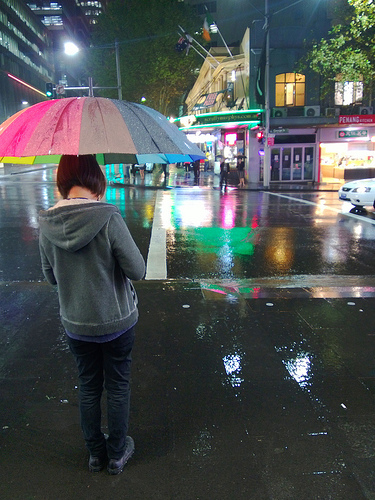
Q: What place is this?
A: It is a sidewalk.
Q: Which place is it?
A: It is a sidewalk.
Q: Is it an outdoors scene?
A: Yes, it is outdoors.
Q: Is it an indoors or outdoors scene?
A: It is outdoors.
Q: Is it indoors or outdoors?
A: It is outdoors.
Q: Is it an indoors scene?
A: No, it is outdoors.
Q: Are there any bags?
A: No, there are no bags.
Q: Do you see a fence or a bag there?
A: No, there are no bags or fences.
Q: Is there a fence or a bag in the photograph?
A: No, there are no bags or fences.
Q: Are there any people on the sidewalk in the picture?
A: Yes, there are people on the sidewalk.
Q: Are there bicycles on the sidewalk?
A: No, there are people on the sidewalk.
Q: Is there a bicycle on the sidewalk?
A: No, there are people on the sidewalk.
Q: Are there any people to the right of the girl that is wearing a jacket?
A: Yes, there are people to the right of the girl.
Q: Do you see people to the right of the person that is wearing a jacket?
A: Yes, there are people to the right of the girl.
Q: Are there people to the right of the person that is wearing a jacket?
A: Yes, there are people to the right of the girl.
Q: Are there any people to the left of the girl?
A: No, the people are to the right of the girl.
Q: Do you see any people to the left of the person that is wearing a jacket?
A: No, the people are to the right of the girl.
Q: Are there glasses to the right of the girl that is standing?
A: No, there are people to the right of the girl.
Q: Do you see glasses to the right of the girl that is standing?
A: No, there are people to the right of the girl.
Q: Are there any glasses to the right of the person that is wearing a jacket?
A: No, there are people to the right of the girl.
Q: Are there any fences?
A: No, there are no fences.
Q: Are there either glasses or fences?
A: No, there are no fences or glasses.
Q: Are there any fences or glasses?
A: No, there are no fences or glasses.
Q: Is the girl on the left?
A: Yes, the girl is on the left of the image.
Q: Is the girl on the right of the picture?
A: No, the girl is on the left of the image.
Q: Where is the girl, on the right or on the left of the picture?
A: The girl is on the left of the image.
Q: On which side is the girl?
A: The girl is on the left of the image.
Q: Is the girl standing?
A: Yes, the girl is standing.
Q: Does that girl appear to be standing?
A: Yes, the girl is standing.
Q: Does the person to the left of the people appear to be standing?
A: Yes, the girl is standing.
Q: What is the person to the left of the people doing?
A: The girl is standing.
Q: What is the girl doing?
A: The girl is standing.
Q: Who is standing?
A: The girl is standing.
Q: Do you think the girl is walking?
A: No, the girl is standing.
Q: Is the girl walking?
A: No, the girl is standing.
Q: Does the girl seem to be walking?
A: No, the girl is standing.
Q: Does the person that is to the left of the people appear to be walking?
A: No, the girl is standing.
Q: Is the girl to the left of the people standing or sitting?
A: The girl is standing.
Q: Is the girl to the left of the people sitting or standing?
A: The girl is standing.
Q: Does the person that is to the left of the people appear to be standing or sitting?
A: The girl is standing.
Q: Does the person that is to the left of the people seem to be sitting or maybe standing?
A: The girl is standing.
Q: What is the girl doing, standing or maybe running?
A: The girl is standing.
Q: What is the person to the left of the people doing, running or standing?
A: The girl is standing.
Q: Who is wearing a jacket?
A: The girl is wearing a jacket.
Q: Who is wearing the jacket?
A: The girl is wearing a jacket.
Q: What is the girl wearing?
A: The girl is wearing a jacket.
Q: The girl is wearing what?
A: The girl is wearing a jacket.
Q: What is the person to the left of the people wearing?
A: The girl is wearing a jacket.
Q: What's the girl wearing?
A: The girl is wearing a jacket.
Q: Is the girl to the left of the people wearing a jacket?
A: Yes, the girl is wearing a jacket.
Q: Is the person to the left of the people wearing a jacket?
A: Yes, the girl is wearing a jacket.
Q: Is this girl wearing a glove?
A: No, the girl is wearing a jacket.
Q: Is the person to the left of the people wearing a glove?
A: No, the girl is wearing a jacket.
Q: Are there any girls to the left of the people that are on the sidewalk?
A: Yes, there is a girl to the left of the people.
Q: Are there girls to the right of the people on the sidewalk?
A: No, the girl is to the left of the people.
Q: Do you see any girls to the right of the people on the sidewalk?
A: No, the girl is to the left of the people.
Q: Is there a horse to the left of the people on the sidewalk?
A: No, there is a girl to the left of the people.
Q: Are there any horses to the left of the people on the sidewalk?
A: No, there is a girl to the left of the people.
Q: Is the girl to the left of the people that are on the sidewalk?
A: Yes, the girl is to the left of the people.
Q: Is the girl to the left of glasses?
A: No, the girl is to the left of the people.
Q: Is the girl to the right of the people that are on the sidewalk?
A: No, the girl is to the left of the people.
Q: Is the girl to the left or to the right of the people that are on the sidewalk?
A: The girl is to the left of the people.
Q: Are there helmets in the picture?
A: No, there are no helmets.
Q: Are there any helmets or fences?
A: No, there are no helmets or fences.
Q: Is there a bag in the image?
A: No, there are no bags.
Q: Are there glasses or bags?
A: No, there are no bags or glasses.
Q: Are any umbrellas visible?
A: Yes, there is an umbrella.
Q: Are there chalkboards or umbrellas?
A: Yes, there is an umbrella.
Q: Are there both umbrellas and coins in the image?
A: No, there is an umbrella but no coins.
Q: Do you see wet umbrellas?
A: Yes, there is a wet umbrella.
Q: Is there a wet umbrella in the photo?
A: Yes, there is a wet umbrella.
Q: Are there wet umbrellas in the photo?
A: Yes, there is a wet umbrella.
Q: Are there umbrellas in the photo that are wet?
A: Yes, there is an umbrella that is wet.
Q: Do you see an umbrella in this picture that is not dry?
A: Yes, there is a wet umbrella.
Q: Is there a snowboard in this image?
A: No, there are no snowboards.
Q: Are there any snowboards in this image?
A: No, there are no snowboards.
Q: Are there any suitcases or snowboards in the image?
A: No, there are no snowboards or suitcases.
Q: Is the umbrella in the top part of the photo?
A: Yes, the umbrella is in the top of the image.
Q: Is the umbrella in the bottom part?
A: No, the umbrella is in the top of the image.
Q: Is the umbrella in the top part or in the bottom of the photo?
A: The umbrella is in the top of the image.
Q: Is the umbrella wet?
A: Yes, the umbrella is wet.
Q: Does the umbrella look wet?
A: Yes, the umbrella is wet.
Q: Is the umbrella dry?
A: No, the umbrella is wet.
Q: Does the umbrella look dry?
A: No, the umbrella is wet.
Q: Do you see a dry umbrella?
A: No, there is an umbrella but it is wet.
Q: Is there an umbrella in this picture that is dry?
A: No, there is an umbrella but it is wet.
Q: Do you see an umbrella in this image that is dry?
A: No, there is an umbrella but it is wet.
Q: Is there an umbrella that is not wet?
A: No, there is an umbrella but it is wet.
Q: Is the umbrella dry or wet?
A: The umbrella is wet.